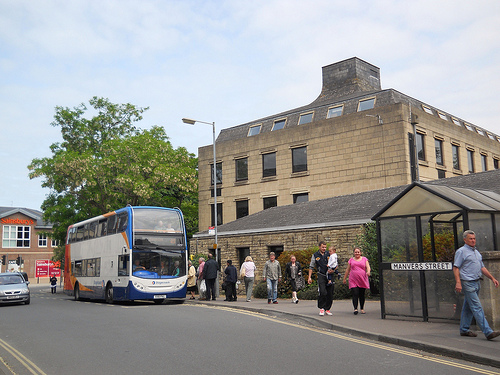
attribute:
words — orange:
[0, 216, 42, 226]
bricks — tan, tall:
[343, 119, 386, 176]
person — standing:
[264, 250, 290, 306]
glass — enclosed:
[355, 195, 428, 320]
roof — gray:
[457, 180, 490, 214]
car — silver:
[1, 274, 31, 307]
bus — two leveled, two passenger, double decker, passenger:
[59, 221, 199, 302]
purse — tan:
[198, 278, 204, 284]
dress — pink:
[346, 258, 372, 290]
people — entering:
[200, 244, 296, 296]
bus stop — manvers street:
[362, 198, 455, 328]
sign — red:
[38, 249, 61, 275]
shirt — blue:
[453, 243, 482, 285]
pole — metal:
[199, 131, 229, 184]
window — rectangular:
[234, 148, 260, 186]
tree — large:
[65, 101, 180, 207]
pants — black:
[347, 278, 372, 311]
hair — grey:
[463, 228, 470, 236]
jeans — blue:
[463, 285, 494, 328]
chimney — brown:
[320, 50, 378, 94]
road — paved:
[164, 304, 220, 361]